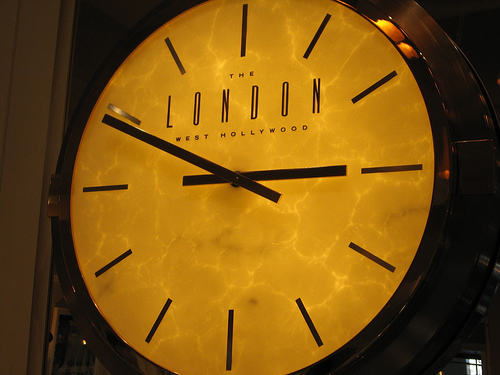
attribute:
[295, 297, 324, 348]
line — Black 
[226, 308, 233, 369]
line — Black 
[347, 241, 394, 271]
line — Black 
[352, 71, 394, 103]
line — Black 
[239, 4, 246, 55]
line — Black 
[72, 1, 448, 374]
clock face — Yellow 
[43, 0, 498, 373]
clock — sleek, Large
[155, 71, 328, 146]
lettering — black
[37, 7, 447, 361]
clock — large, black, yellow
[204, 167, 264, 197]
bolt — black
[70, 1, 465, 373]
clock — Large , Round 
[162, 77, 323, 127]
name — the london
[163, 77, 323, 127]
london — black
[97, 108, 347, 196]
hand — black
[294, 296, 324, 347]
mark — tick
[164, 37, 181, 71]
mark — tick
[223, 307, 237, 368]
dash — black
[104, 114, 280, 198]
hand — big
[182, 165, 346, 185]
hand — small